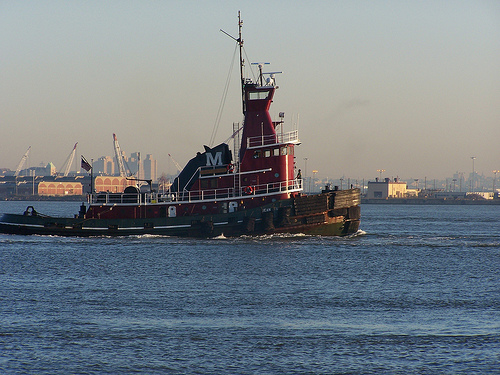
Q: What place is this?
A: It is an ocean.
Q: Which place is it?
A: It is an ocean.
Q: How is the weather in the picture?
A: It is cloudy.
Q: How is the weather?
A: It is cloudy.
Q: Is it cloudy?
A: Yes, it is cloudy.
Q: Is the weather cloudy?
A: Yes, it is cloudy.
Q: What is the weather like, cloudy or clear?
A: It is cloudy.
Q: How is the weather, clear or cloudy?
A: It is cloudy.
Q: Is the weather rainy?
A: No, it is cloudy.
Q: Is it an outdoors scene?
A: Yes, it is outdoors.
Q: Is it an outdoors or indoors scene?
A: It is outdoors.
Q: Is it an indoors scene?
A: No, it is outdoors.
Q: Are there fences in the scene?
A: No, there are no fences.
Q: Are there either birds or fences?
A: No, there are no fences or birds.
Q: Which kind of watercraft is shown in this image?
A: The watercraft is a ship.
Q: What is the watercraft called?
A: The watercraft is a ship.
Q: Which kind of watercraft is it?
A: The watercraft is a ship.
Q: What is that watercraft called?
A: This is a ship.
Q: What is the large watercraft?
A: The watercraft is a ship.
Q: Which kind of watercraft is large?
A: The watercraft is a ship.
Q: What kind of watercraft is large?
A: The watercraft is a ship.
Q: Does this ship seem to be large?
A: Yes, the ship is large.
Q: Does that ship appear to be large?
A: Yes, the ship is large.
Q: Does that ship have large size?
A: Yes, the ship is large.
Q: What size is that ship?
A: The ship is large.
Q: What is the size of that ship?
A: The ship is large.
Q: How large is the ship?
A: The ship is large.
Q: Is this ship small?
A: No, the ship is large.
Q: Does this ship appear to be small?
A: No, the ship is large.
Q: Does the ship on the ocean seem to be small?
A: No, the ship is large.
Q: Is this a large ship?
A: Yes, this is a large ship.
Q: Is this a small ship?
A: No, this is a large ship.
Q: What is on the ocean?
A: The ship is on the ocean.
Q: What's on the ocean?
A: The ship is on the ocean.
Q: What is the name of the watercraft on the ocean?
A: The watercraft is a ship.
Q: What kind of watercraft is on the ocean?
A: The watercraft is a ship.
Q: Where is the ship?
A: The ship is on the ocean.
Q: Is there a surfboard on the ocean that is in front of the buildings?
A: No, there is a ship on the ocean.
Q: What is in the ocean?
A: The ship is in the ocean.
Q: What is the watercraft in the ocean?
A: The watercraft is a ship.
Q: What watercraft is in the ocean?
A: The watercraft is a ship.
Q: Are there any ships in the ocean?
A: Yes, there is a ship in the ocean.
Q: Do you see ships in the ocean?
A: Yes, there is a ship in the ocean.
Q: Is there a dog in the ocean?
A: No, there is a ship in the ocean.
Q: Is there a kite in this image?
A: No, there are no kites.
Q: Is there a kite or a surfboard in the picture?
A: No, there are no kites or surfboards.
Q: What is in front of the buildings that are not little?
A: The ocean is in front of the buildings.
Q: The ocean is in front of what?
A: The ocean is in front of the buildings.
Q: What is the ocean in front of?
A: The ocean is in front of the buildings.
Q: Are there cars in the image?
A: No, there are no cars.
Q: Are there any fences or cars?
A: No, there are no cars or fences.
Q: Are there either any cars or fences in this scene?
A: No, there are no cars or fences.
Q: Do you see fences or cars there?
A: No, there are no cars or fences.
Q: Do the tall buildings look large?
A: Yes, the buildings are large.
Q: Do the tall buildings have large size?
A: Yes, the buildings are large.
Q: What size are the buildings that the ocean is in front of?
A: The buildings are large.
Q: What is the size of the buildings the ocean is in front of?
A: The buildings are large.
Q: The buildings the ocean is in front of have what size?
A: The buildings are large.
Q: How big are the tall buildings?
A: The buildings are large.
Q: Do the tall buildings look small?
A: No, the buildings are large.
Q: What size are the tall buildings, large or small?
A: The buildings are large.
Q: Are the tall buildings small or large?
A: The buildings are large.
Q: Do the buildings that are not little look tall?
A: Yes, the buildings are tall.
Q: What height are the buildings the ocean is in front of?
A: The buildings are tall.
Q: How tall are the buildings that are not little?
A: The buildings are tall.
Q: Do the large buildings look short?
A: No, the buildings are tall.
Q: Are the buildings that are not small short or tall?
A: The buildings are tall.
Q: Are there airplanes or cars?
A: No, there are no cars or airplanes.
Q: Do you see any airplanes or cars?
A: No, there are no cars or airplanes.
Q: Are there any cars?
A: No, there are no cars.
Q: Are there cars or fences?
A: No, there are no cars or fences.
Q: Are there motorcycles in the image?
A: No, there are no motorcycles.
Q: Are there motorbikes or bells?
A: No, there are no motorbikes or bells.